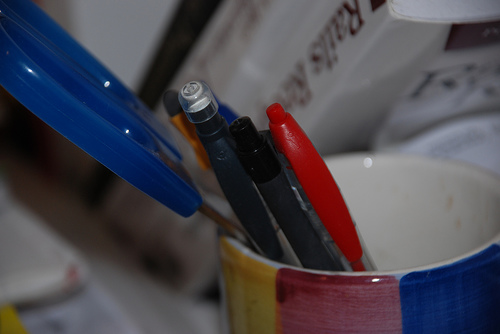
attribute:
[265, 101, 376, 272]
pen — red, plastic, grey, black, writing tool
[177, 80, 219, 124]
cap — clear, plastic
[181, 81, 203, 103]
eraser — white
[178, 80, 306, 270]
pencil — black, mechanical, grey, writing tool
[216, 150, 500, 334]
coffee mug — multi-colored, round, striped, colorful, blue, yellow, red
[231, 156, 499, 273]
mouth — white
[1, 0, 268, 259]
scissors — blue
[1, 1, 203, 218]
handle — blue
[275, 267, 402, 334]
paint — red, stripe, pink, wide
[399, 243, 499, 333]
paint — blue, stripe, wide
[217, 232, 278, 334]
paint — yellow, stripe, wide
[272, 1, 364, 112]
writing — black, blurry, burgundy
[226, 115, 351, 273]
pen — writing tool, black, grey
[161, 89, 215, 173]
pencil — orange, writing tool, yellow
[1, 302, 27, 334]
paper — yellow, bright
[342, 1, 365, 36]
letter — r, burgundy